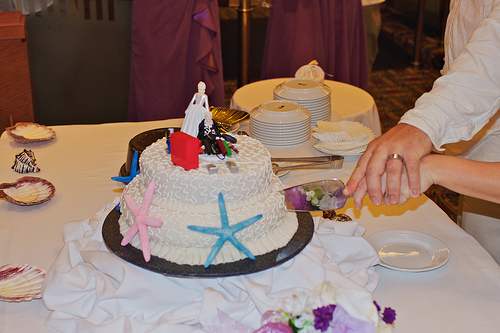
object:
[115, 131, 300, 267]
cake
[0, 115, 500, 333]
table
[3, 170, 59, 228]
shell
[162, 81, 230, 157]
topper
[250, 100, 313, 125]
saucer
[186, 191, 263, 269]
starfish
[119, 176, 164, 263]
starfish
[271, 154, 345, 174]
tong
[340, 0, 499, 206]
man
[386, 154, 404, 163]
ring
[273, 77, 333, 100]
plate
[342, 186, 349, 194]
nail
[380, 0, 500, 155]
shirt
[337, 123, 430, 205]
hand